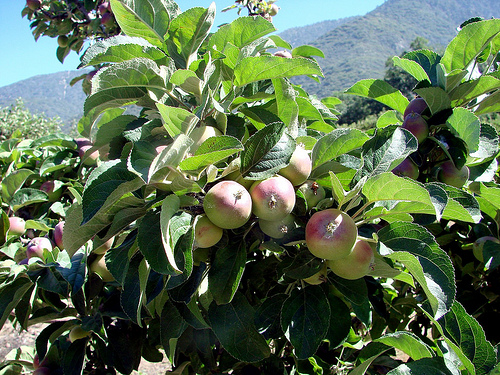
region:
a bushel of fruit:
[157, 127, 409, 288]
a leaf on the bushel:
[339, 76, 407, 116]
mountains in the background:
[0, 1, 499, 133]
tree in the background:
[0, 103, 72, 140]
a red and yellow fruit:
[303, 207, 359, 259]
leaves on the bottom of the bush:
[3, 274, 497, 373]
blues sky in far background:
[1, 1, 87, 84]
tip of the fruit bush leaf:
[426, 296, 455, 324]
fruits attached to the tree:
[156, 159, 403, 298]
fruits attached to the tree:
[129, 140, 425, 303]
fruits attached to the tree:
[173, 136, 356, 269]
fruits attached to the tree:
[146, 150, 386, 279]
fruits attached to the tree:
[158, 143, 469, 303]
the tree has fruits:
[148, 146, 408, 313]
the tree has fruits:
[172, 127, 380, 303]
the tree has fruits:
[164, 139, 377, 296]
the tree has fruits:
[148, 115, 396, 292]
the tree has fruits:
[116, 108, 427, 334]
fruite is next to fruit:
[305, 211, 357, 262]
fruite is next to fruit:
[326, 238, 371, 280]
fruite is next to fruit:
[303, 271, 325, 286]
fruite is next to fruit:
[248, 177, 295, 224]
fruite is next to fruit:
[202, 181, 250, 228]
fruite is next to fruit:
[192, 217, 222, 249]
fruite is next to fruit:
[6, 214, 28, 235]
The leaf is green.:
[203, 13, 278, 64]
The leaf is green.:
[162, 2, 221, 71]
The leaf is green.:
[110, 1, 175, 62]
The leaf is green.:
[228, 50, 328, 92]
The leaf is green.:
[83, 54, 183, 103]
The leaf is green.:
[178, 133, 245, 172]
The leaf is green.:
[238, 112, 302, 182]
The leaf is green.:
[133, 190, 186, 282]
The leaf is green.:
[271, 280, 336, 365]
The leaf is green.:
[203, 223, 253, 312]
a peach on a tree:
[206, 181, 251, 230]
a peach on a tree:
[250, 171, 296, 225]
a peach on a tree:
[305, 208, 357, 260]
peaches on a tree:
[185, 147, 372, 289]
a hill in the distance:
[0, 1, 499, 131]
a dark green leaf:
[78, 161, 127, 229]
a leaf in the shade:
[210, 298, 272, 366]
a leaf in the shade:
[280, 285, 325, 360]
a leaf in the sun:
[228, 58, 326, 81]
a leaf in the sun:
[80, 36, 164, 69]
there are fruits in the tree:
[135, 61, 393, 308]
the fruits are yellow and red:
[295, 200, 379, 287]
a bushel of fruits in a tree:
[174, 119, 334, 284]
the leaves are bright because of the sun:
[92, 3, 369, 223]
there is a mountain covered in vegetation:
[9, 0, 494, 161]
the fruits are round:
[300, 196, 370, 266]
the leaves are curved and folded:
[376, 215, 484, 334]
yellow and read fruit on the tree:
[201, 177, 251, 232]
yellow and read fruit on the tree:
[245, 165, 291, 226]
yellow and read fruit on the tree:
[302, 203, 354, 263]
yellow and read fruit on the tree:
[325, 236, 375, 278]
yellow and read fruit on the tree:
[253, 210, 294, 238]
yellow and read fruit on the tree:
[18, 232, 58, 263]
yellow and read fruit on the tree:
[7, 215, 27, 235]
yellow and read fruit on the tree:
[436, 156, 468, 189]